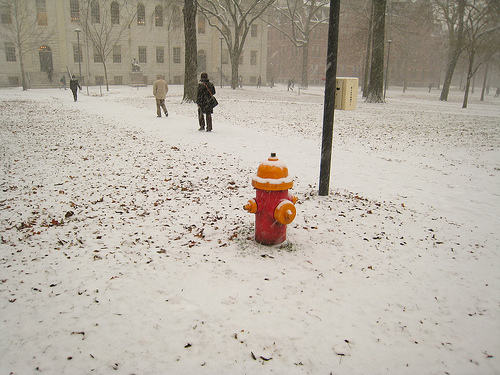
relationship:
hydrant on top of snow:
[244, 153, 297, 248] [1, 83, 499, 374]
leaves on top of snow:
[1, 100, 499, 374] [1, 83, 499, 374]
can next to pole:
[333, 76, 359, 110] [381, 38, 391, 102]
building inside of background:
[0, 3, 271, 87] [1, 2, 499, 91]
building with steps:
[0, 3, 271, 87] [25, 70, 71, 88]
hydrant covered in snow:
[244, 153, 297, 248] [1, 83, 499, 374]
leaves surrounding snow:
[1, 100, 499, 374] [1, 83, 499, 374]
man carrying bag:
[198, 71, 217, 132] [199, 79, 218, 112]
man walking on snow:
[198, 71, 217, 132] [1, 83, 499, 374]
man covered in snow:
[198, 71, 217, 132] [1, 83, 499, 374]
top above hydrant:
[251, 151, 295, 192] [244, 153, 297, 248]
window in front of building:
[70, 0, 82, 26] [0, 3, 271, 87]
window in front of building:
[35, 2, 50, 27] [0, 3, 271, 87]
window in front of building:
[73, 42, 84, 61] [0, 3, 271, 87]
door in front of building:
[39, 45, 55, 83] [0, 3, 271, 87]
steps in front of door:
[25, 70, 71, 88] [39, 45, 55, 83]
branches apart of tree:
[194, 0, 276, 55] [198, 2, 276, 89]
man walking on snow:
[69, 74, 83, 100] [1, 83, 499, 374]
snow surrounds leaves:
[1, 83, 499, 374] [1, 100, 499, 374]